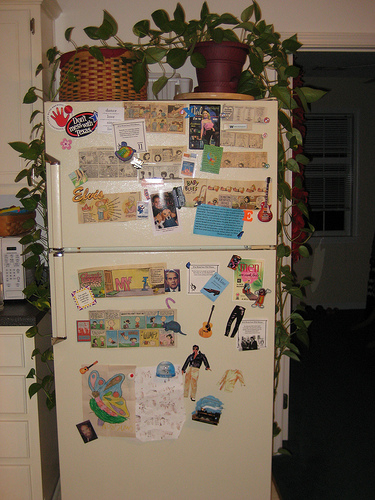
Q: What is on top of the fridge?
A: Plants.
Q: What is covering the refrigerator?
A: Magnets.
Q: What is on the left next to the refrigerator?
A: Cabinet.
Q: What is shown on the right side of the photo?
A: Window.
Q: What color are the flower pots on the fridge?
A: Brown.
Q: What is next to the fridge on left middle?
A: Microwave.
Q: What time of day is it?
A: Night.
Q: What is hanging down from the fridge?
A: Plant.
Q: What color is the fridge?
A: White.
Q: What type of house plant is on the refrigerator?
A: Vine.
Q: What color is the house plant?
A: Green.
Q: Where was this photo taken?
A: Kitchen.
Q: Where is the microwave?
A: On the countertop.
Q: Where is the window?
A: In the dark room.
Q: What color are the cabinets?
A: White.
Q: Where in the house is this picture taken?
A: The kitchen.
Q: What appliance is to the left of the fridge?
A: A microwave.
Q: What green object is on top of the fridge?
A: A plant.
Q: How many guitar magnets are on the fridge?
A: Three.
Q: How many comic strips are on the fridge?
A: Ten.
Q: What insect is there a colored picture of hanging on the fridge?
A: A butterfly.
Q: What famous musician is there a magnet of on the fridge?
A: Elvis Presley.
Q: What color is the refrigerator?
A: White.